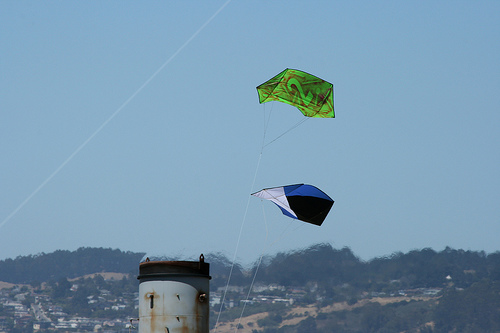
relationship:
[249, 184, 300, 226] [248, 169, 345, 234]
white part of kite